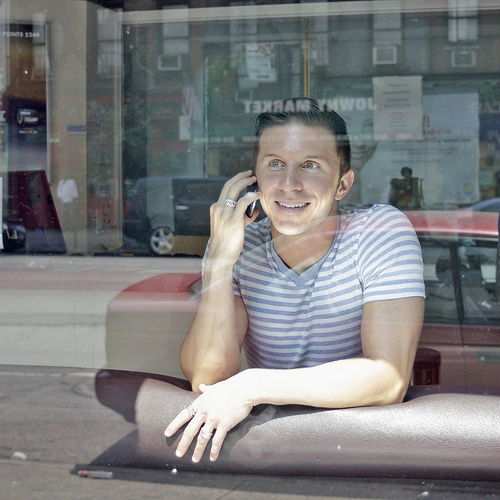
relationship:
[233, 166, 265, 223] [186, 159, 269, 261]
cell phone in hand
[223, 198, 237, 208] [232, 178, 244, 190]
ring on finger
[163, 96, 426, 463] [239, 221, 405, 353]
he wears shirt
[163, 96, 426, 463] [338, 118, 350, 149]
he has hair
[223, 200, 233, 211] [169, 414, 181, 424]
ring on finger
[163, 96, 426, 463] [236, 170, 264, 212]
he talking on phone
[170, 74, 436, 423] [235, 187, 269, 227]
he holding phone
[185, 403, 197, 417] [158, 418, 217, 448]
ring on fingers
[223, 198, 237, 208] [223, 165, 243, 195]
ring on finger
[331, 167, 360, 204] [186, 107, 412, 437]
ear on man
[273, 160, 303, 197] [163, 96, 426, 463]
nose on he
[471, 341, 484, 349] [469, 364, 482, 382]
handle on door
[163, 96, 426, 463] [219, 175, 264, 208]
he on phone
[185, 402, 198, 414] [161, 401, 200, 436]
ring around finger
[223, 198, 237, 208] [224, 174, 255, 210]
ring around finger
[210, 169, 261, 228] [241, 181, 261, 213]
fingers around phone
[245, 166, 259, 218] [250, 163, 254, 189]
cell phone lifted up to ear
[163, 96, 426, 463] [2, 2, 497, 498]
he behind window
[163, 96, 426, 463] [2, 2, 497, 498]
he looking through window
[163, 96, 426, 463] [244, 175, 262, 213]
he talking on cellphone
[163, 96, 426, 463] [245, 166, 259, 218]
he holding cell phone